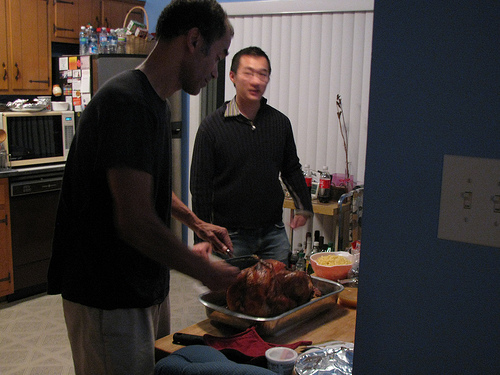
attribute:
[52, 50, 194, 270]
refrigerator — silver, black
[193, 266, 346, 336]
tray — metal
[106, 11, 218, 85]
basket — wicker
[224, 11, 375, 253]
blinds — long, white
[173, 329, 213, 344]
handle — black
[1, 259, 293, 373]
floor — grey, beige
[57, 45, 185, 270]
refrigerator — black, silver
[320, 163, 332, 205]
bottle — clear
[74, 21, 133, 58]
bottles — water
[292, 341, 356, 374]
aluminum paper — crumpled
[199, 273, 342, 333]
pan — silver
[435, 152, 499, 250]
panel — white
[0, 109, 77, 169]
microwave oven — white trimmed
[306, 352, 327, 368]
foil — aluminum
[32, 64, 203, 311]
shirt — black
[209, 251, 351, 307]
turkey — roasted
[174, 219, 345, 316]
turkey — brown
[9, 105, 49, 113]
dish — white